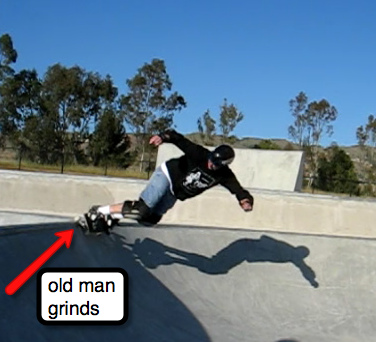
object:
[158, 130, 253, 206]
sweatshirt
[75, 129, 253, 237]
man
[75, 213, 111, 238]
skateboard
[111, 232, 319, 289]
shadow